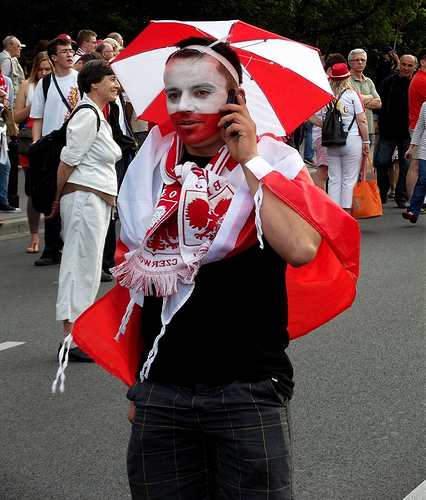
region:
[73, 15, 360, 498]
Man with umbrella hat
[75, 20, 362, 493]
Man with black shirt and pants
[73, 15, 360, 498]
Man with red and white face paint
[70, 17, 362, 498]
Man on a cell phone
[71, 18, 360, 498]
Man wearing red and white scarf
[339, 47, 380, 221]
Man crossing his arms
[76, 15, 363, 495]
Man wearing red and white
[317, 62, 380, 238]
Woman holding orange bag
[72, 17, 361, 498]
Man holding phone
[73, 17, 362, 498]
Teen wearing red and white sunhat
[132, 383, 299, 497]
the pants are blue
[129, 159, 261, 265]
the scarf is from chelsea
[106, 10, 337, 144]
the umbrella is red and white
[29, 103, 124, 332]
her clothes are white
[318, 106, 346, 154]
her bag is black in color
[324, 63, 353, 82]
her hat is red in color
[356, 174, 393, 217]
the bag is orange in color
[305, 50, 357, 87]
the lady is wearing a red hat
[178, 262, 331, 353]
the mman is wearing a black tshirt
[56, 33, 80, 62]
the man is wearing glasses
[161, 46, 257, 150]
man's face is painted white and red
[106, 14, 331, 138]
man has a mini umbrella hat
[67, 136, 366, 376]
man has a red and white flag around him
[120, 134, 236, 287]
scarf is red and white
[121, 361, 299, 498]
man is wearing plaid pants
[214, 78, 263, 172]
man is on the phone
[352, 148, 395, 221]
woman is carrying a bag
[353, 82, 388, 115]
man has his arms folded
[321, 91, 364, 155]
girl is carrying a backpack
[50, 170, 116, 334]
woman is wearing white pants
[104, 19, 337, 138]
the opened umbrella on the man's head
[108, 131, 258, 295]
the scarf around the man's neck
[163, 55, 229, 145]
the paint on the man's face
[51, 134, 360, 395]
the fabric wrapped around the man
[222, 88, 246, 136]
the phone to the man's ear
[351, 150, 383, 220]
the orange bag in the back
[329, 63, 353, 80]
the red hat on the woman's head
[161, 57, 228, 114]
the white paint on the man's face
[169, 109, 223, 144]
the red paint on the man's face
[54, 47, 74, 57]
the glasses on the man's face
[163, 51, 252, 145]
the head of a man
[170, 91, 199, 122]
the nose o fa man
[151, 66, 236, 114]
the eyes of a man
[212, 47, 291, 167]
the hand of a man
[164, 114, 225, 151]
the lips of a man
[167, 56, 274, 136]
a man with a painted face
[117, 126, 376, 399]
a man wearing a shirt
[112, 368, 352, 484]
a man wearing shorts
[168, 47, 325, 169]
a man on the phone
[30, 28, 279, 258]
people in the back ground